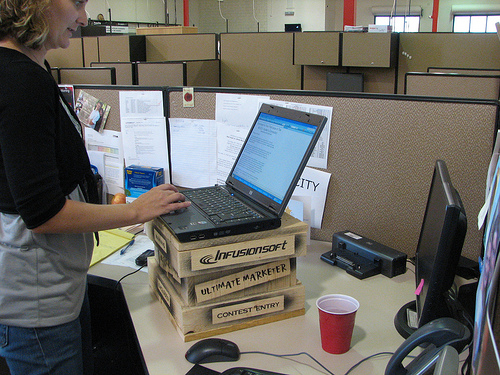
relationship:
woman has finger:
[2, 1, 187, 374] [140, 182, 188, 216]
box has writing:
[154, 227, 310, 333] [204, 240, 298, 320]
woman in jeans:
[2, 1, 187, 374] [3, 281, 91, 374]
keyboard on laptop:
[153, 183, 267, 241] [156, 99, 326, 247]